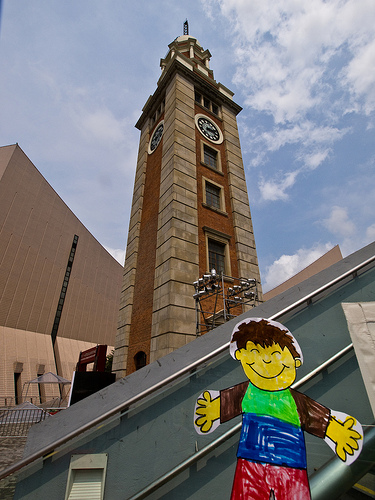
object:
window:
[203, 142, 219, 173]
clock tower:
[111, 18, 263, 382]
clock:
[194, 113, 223, 145]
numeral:
[207, 131, 213, 139]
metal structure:
[192, 268, 264, 339]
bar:
[51, 233, 80, 396]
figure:
[191, 318, 363, 500]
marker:
[255, 432, 282, 461]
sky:
[0, 0, 375, 297]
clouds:
[0, 0, 375, 296]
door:
[202, 174, 228, 218]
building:
[111, 18, 263, 377]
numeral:
[211, 125, 214, 130]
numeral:
[198, 121, 202, 125]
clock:
[148, 120, 165, 155]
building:
[0, 142, 124, 405]